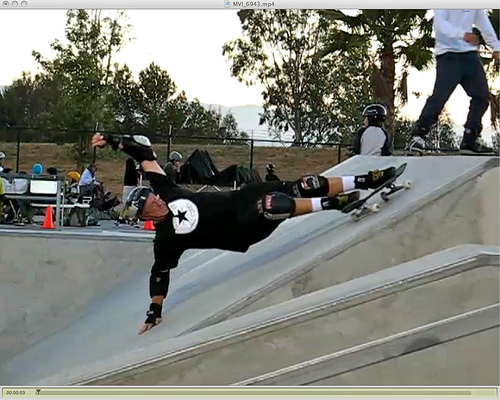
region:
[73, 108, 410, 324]
skater doing a trick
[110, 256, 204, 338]
black wrist and elbow pads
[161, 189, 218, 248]
white circle with black star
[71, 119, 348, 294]
skater wearing mostly black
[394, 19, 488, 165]
man with white shirt and grey pants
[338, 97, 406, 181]
skater wearing a black helmet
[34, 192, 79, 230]
orange caution cone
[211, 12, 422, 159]
tall green trees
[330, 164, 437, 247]
skateboard with white wheels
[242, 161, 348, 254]
black and white kneepads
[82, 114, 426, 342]
A man on a skateboard.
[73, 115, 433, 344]
The gentleman is older.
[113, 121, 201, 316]
Man wearing elbow guards.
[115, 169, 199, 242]
Man wearing a helmet.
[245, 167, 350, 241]
The man is wearing knee guards.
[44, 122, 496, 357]
The man is on a ramp.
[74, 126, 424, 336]
The man has one hand on the ground.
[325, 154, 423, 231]
The skateboard has wheels.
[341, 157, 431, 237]
The wheels are white.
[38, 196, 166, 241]
Orange safety cones in place.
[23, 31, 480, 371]
People at a skateboard park.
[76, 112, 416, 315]
An older man skateboarding.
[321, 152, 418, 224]
A pair of black tennis shoes.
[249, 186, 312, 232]
Protective knee pad on right knee.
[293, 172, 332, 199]
Protective knee pad on left knee.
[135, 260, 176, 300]
Protective elbow pad on right elbow.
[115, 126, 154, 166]
Protective elbow pad on left elbow.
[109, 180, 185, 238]
Protective safety helmet.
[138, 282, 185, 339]
Black glove on right hand.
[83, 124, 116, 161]
Black glove on left hand.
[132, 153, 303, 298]
a man in black shirt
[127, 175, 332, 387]
a man in black shirt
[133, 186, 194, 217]
older man is skateboarder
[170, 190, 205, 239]
white circle with star on shirt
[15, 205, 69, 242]
orange safety cone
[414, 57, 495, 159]
skateboarder on top of skate ramp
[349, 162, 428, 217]
skateboard wheels are white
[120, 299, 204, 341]
skateboarder's hand on the ramp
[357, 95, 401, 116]
helmet is black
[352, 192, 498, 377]
three skateboarding ramps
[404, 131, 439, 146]
white shoe laces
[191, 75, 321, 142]
hills between the trees